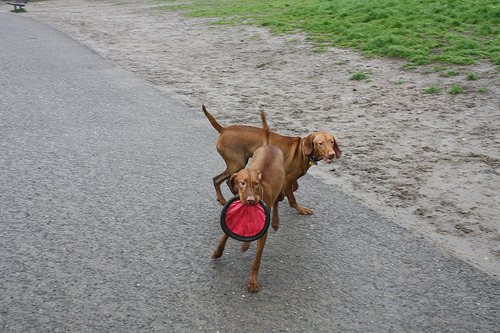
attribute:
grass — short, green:
[270, 5, 489, 74]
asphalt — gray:
[0, 12, 499, 331]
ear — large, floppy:
[298, 133, 316, 158]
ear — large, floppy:
[332, 135, 344, 162]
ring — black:
[218, 193, 271, 244]